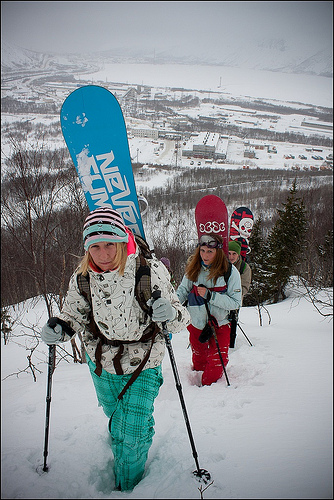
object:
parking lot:
[229, 135, 332, 168]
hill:
[0, 281, 334, 499]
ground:
[0, 0, 334, 215]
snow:
[97, 63, 334, 105]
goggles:
[200, 235, 219, 248]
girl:
[176, 233, 242, 387]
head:
[199, 234, 220, 266]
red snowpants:
[186, 326, 230, 385]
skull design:
[229, 216, 254, 245]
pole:
[41, 316, 56, 471]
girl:
[38, 194, 190, 493]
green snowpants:
[82, 352, 164, 493]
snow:
[46, 328, 285, 496]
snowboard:
[58, 78, 145, 260]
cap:
[82, 206, 128, 251]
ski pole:
[151, 285, 201, 479]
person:
[220, 240, 252, 349]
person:
[175, 232, 243, 390]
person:
[40, 204, 188, 494]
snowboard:
[229, 206, 254, 264]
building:
[180, 132, 231, 161]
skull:
[239, 216, 252, 239]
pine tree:
[258, 194, 309, 301]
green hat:
[227, 240, 242, 257]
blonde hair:
[78, 243, 126, 276]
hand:
[39, 320, 64, 346]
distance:
[247, 159, 321, 258]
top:
[57, 83, 122, 125]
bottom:
[220, 145, 313, 208]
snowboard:
[194, 194, 228, 257]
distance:
[121, 64, 328, 128]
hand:
[146, 296, 176, 323]